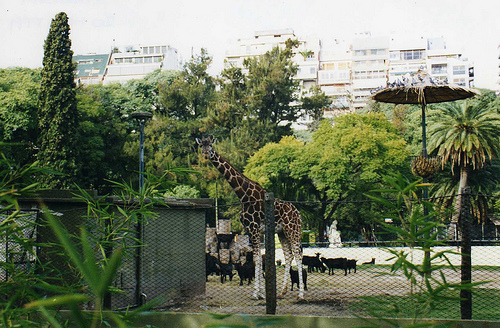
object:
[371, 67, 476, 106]
umbrella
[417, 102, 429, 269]
pole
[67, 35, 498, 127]
building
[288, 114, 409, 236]
tree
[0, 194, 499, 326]
fence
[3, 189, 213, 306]
shed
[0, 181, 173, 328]
green plants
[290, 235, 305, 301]
leg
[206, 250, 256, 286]
goats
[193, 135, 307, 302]
giraffe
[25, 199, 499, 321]
fence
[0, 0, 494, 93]
sky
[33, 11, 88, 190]
leaves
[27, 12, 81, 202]
tree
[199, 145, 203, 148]
eye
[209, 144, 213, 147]
eye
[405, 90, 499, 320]
tree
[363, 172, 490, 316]
leaves